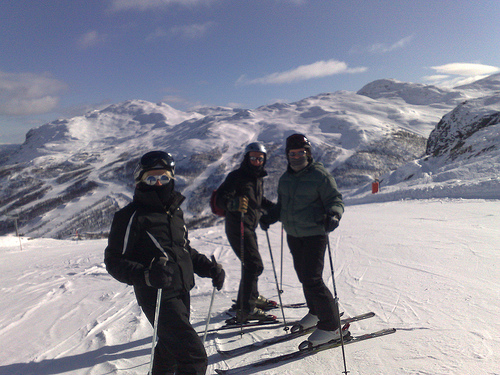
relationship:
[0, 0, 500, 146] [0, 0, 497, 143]
cloud in sky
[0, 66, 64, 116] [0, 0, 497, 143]
cloud in sky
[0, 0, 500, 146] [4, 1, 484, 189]
cloud in sky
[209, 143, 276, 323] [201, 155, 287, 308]
person in outfit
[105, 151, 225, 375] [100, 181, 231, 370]
person in outfit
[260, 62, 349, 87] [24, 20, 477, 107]
cloud in sky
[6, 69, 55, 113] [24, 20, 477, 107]
cloud in sky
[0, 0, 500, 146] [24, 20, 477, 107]
cloud in sky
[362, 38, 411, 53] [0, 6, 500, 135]
cloud in sky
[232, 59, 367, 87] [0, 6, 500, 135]
cloud in sky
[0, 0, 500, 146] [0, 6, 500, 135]
cloud in sky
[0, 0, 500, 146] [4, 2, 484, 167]
cloud in sky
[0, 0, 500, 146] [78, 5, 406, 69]
cloud in sky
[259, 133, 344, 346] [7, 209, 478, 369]
person skiing down hillside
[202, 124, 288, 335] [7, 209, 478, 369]
person skiing down hillside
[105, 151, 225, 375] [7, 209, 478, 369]
person skiing down hillside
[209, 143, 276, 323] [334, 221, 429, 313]
person skiing down hill side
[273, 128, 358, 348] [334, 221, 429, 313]
person skiing down hill side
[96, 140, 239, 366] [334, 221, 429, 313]
person skiing down hill side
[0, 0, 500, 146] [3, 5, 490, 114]
cloud in sky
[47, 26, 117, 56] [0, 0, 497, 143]
cloud in sky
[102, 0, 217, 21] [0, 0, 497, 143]
cloud in sky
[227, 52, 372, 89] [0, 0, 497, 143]
cloud in sky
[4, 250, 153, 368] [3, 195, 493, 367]
tracks in snow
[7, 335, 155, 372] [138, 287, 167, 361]
shadow in snow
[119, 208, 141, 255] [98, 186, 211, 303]
stripe on coat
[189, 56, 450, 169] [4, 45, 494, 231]
mountain in background